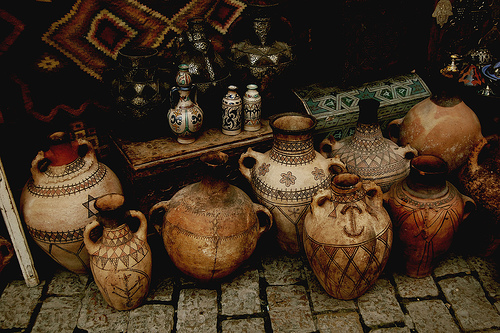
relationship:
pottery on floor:
[159, 183, 267, 292] [0, 255, 499, 331]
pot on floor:
[311, 184, 404, 296] [0, 255, 499, 331]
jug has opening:
[236, 101, 328, 273] [279, 116, 314, 130]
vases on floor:
[61, 115, 500, 326] [0, 255, 499, 331]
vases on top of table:
[61, 115, 500, 326] [107, 78, 372, 165]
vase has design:
[395, 150, 462, 296] [410, 213, 445, 270]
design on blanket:
[68, 7, 154, 37] [9, 13, 267, 99]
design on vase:
[410, 213, 445, 270] [395, 150, 462, 296]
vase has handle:
[395, 150, 462, 296] [455, 187, 477, 231]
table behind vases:
[107, 78, 372, 165] [61, 115, 500, 326]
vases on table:
[104, 36, 291, 130] [107, 114, 271, 197]